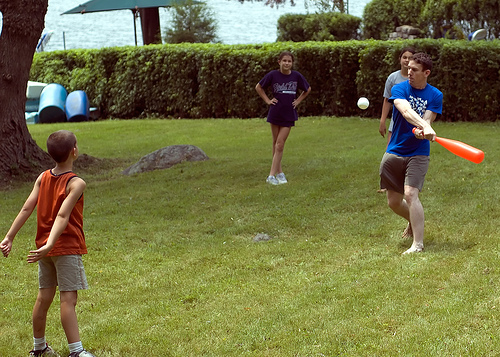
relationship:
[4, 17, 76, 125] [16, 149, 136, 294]
tree next to person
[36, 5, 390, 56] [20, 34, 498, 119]
water behind hedge